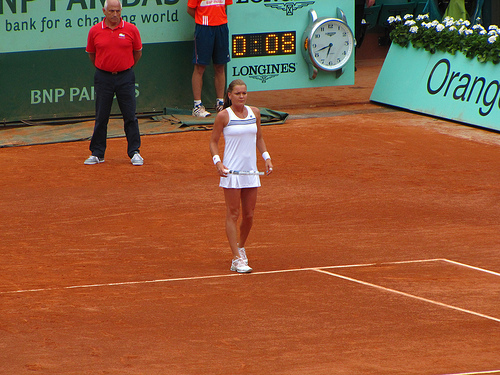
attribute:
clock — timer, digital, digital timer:
[231, 30, 295, 59]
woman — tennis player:
[210, 80, 273, 273]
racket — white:
[223, 169, 265, 176]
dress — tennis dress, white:
[218, 106, 263, 189]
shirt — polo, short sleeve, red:
[83, 16, 143, 74]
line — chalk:
[310, 257, 445, 270]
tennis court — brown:
[5, 109, 497, 374]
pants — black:
[89, 68, 140, 156]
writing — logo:
[232, 62, 296, 76]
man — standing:
[82, 0, 143, 166]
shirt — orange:
[187, 0, 233, 26]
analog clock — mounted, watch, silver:
[301, 8, 357, 80]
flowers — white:
[387, 14, 499, 61]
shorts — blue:
[193, 22, 230, 64]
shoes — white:
[230, 246, 253, 274]